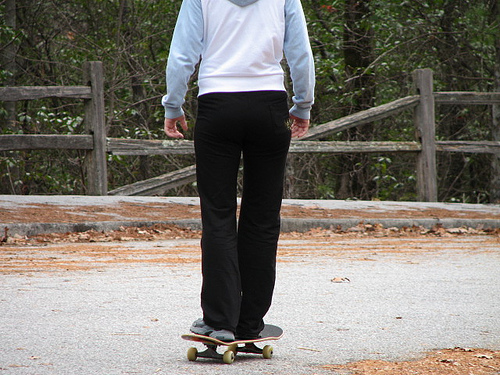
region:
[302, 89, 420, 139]
broke post on wooden fence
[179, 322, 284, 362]
yellow wheels on black skateboard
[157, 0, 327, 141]
person wearing white shirt over blue sweater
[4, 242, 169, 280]
dead brush on side of street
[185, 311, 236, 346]
grey tennis shoe on left foot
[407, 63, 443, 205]
wood fence post with two slats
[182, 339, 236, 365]
two yellow wheels on back of skateboard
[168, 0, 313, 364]
person in black pants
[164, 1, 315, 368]
person in black pants riding skateboard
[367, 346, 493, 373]
brown dead leaves on road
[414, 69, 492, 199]
wood fence on side of road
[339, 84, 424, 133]
broke post on wood fence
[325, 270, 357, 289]
brown dead leaf in middle of road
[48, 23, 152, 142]
dead tree behind wood fence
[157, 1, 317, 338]
person in white shirt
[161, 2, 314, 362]
person in white shirt on skateboard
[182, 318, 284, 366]
black skateboard with yellow wheels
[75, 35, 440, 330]
the person looks awkward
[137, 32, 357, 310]
this is a person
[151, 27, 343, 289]
the person is skateboarding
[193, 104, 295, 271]
the pants are black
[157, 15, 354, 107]
the sweater is blue and white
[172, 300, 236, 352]
the shoes are grey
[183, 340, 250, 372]
the wheels are white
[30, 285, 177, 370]
the pavement is gray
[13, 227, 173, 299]
the ground is orange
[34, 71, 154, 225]
the fence is picket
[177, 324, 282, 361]
A black skateboard with dull yellow wheels.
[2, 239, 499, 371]
Grey paved road.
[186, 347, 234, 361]
Back two dull yellow wheels.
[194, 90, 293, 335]
Black pants a person has on.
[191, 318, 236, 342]
A persons let white and grey shoe.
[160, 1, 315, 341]
A person on a skateboard in black pants.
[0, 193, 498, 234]
A grey sidewalk covered in leaves.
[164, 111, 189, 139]
A persons left hand.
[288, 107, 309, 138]
A persons right hand.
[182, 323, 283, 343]
Black top of a skateboard.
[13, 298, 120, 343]
blue color on the path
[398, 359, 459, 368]
red clay on the ground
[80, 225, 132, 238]
dry yellow leaves on the ground